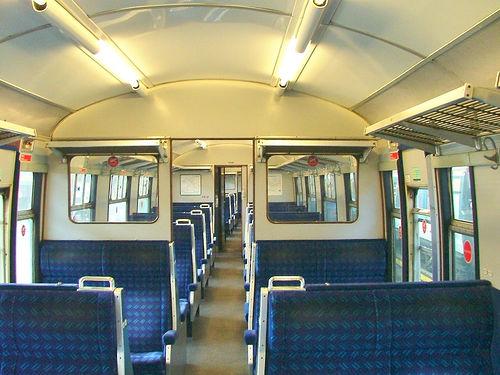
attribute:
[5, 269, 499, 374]
chairs — row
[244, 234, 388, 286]
seat — blue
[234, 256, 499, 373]
seat — blue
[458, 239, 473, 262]
sticker — red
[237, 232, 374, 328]
seats — blue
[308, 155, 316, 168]
sticker — red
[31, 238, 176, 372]
bench — covered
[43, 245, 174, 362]
bench — covered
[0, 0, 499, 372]
passenger wagon — empty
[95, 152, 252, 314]
chairs — row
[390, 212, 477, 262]
stickers — red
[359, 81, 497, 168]
shelf — above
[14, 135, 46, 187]
sticker — red